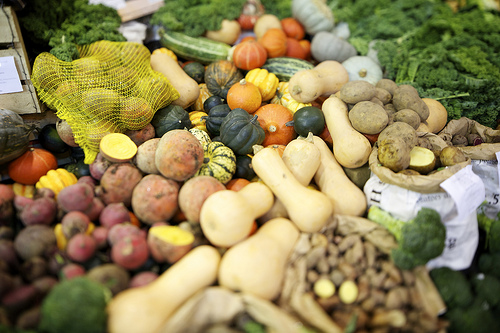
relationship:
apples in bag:
[31, 40, 180, 165] [28, 30, 182, 173]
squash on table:
[235, 150, 330, 223] [27, 36, 442, 308]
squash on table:
[202, 180, 273, 245] [53, 55, 404, 305]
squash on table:
[228, 215, 298, 291] [39, 22, 409, 302]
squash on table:
[106, 249, 224, 328] [50, 16, 428, 308]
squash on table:
[320, 93, 373, 169] [50, 16, 428, 308]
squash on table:
[240, 128, 305, 209] [48, 16, 497, 306]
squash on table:
[311, 93, 368, 154] [50, 16, 428, 308]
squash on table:
[282, 57, 349, 103] [48, 16, 497, 306]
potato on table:
[368, 117, 423, 163] [48, 16, 497, 306]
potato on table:
[342, 96, 393, 133] [48, 16, 497, 306]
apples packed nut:
[38, 46, 154, 112] [35, 39, 165, 120]